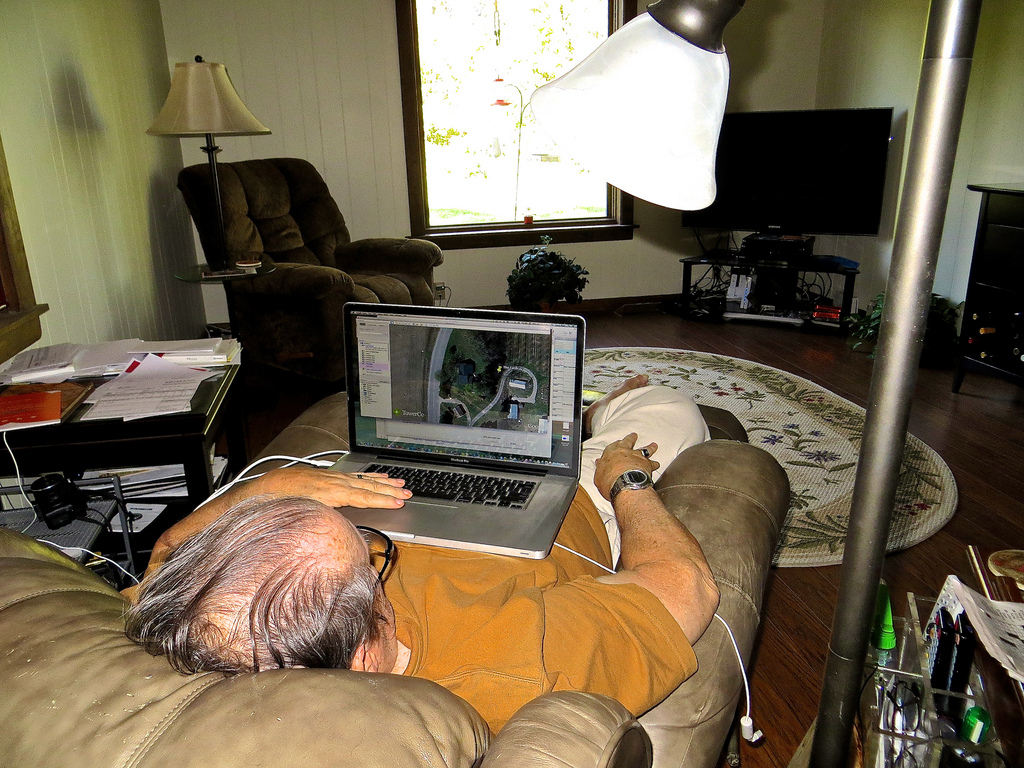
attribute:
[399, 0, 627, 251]
window — large 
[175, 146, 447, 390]
recliner — dark 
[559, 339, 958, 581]
area rug — large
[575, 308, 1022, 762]
floor — wooden 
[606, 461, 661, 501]
wrist — man's wrist.